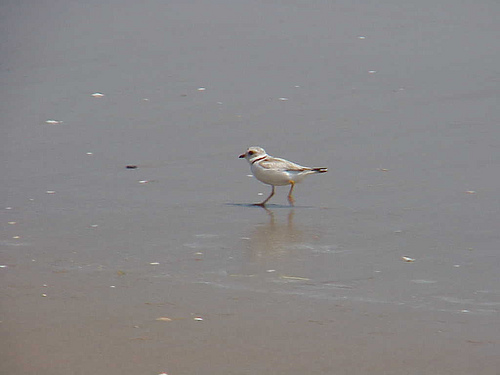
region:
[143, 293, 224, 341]
seashells in the wet sand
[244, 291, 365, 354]
wet sand on the beach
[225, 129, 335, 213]
bird walking on the beach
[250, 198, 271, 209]
bird's foot down in the sand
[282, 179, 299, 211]
bird's foot raised in the air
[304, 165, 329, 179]
tail feathers on the bird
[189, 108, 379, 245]
bird at the beach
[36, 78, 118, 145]
white seashells on the beach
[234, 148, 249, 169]
bird beak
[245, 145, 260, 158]
bird's eye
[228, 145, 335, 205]
a bird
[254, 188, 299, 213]
legs of the bird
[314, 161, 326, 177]
the tail of the bird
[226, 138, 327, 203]
the bird is standing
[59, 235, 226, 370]
the sand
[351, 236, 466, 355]
the sand is wet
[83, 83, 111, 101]
a seashell in the sand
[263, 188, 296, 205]
the legs on the bird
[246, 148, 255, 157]
the birds eye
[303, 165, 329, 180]
the birds tail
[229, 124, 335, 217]
white bird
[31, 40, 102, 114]
white clouds in blue sky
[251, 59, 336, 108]
white clouds in blue sky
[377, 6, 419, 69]
white clouds in blue sky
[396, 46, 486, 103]
white clouds in blue sky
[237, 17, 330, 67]
white clouds in blue sky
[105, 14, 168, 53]
white clouds in blue sky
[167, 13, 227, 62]
white clouds in blue sky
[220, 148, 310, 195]
gray bird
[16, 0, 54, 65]
white clouds in blue sky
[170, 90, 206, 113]
white clouds in blue sky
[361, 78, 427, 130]
white clouds in blue sky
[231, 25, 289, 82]
white clouds in blue sky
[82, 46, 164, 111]
white clouds in blue sky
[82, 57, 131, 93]
white clouds in blue sky